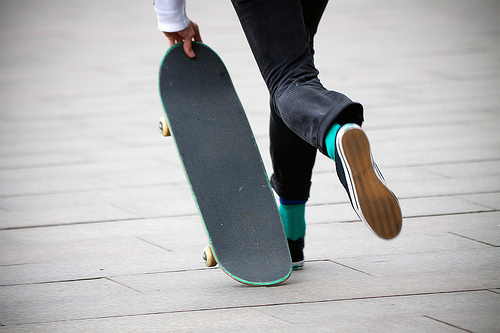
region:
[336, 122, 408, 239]
The bottom of a shoe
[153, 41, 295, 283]
A black top skateboard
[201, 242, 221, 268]
The white wheel of a skateboard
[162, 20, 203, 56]
A person's left hand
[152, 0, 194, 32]
A white long shirt sleeve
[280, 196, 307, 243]
Long light blue socks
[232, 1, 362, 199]
A pair of tight black pants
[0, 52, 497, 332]
A light gray sidewalk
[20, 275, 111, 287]
A crack on the brick ground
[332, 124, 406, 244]
A converse shoe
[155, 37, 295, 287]
A WOODEN SKATEBOARD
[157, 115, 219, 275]
TWO YELLOW SKATEBOARD WHEELS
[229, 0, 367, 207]
A PAIR OF BLACK PANTS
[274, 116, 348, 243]
A PAIR OF AQUA SOCKS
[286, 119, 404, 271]
A PAIR OF BLACK SHOES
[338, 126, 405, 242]
A SHOES RUBBER SOLE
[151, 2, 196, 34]
PART OF A WHITE SLEEVE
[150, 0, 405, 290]
SOMEONE HOLDING A SKATEBOARD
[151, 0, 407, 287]
SOMEONE RUNNING WITH A SKATEBOARD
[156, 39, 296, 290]
A GREEN RIM AROUND THE SKATEBOARD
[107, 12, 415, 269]
a skateboard for riding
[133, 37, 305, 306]
the skateboard is gray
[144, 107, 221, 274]
the wheels are yellow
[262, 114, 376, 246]
this person has blue socks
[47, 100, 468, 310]
the concrete bricks are gray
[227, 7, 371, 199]
this person has on dark blue pants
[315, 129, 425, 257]
the bottom of a tennis shoe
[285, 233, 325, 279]
this shoe is black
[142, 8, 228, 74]
a hand holding a skateboard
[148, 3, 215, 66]
this person has on a white long sleeve shirt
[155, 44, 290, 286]
a black skateboard with green trim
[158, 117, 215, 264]
yellow wheels on the skateboard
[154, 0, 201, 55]
person's left hand holding the board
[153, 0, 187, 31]
a white shirt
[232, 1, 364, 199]
black pants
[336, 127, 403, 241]
the bottom of the left tennis shoe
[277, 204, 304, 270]
the right foot on the ground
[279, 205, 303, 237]
a green right sock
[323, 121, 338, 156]
green left sock in the air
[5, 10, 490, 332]
a gray tile brick sidewalk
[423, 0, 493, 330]
gray cement rectagle shaped blocks used as pavement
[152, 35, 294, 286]
black skateboard with blue edge and tan wheels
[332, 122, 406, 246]
sole of black and white sneaker on a foot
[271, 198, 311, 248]
blue sock in a black and white sneaker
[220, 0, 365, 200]
black pants on a skateboarder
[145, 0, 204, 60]
left hand and wrist of a skateboarder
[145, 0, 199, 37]
white arm of a sweater on skateboarder's left arm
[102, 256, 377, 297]
cement rectangle of gray paver with foot on it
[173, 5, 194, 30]
seam in the white cuff of a sweater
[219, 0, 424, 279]
legs of skateboarder with black pants